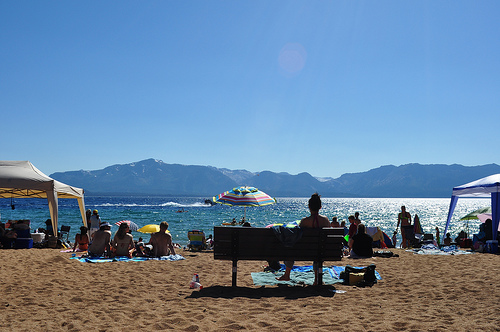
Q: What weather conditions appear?
A: It is cloudless.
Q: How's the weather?
A: It is cloudless.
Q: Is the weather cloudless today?
A: Yes, it is cloudless.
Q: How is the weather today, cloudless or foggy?
A: It is cloudless.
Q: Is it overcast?
A: No, it is cloudless.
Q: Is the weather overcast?
A: No, it is cloudless.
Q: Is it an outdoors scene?
A: Yes, it is outdoors.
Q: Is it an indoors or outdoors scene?
A: It is outdoors.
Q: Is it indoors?
A: No, it is outdoors.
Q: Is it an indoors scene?
A: No, it is outdoors.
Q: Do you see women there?
A: Yes, there is a woman.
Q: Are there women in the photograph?
A: Yes, there is a woman.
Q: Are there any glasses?
A: No, there are no glasses.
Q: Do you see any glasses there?
A: No, there are no glasses.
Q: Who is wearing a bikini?
A: The woman is wearing a bikini.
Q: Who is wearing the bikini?
A: The woman is wearing a bikini.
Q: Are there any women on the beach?
A: Yes, there is a woman on the beach.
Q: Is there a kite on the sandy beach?
A: No, there is a woman on the beach.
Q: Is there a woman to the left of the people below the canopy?
A: Yes, there is a woman to the left of the people.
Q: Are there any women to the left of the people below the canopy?
A: Yes, there is a woman to the left of the people.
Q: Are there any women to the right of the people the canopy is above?
A: No, the woman is to the left of the people.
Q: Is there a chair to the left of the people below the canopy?
A: No, there is a woman to the left of the people.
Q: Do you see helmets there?
A: No, there are no helmets.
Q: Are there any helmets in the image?
A: No, there are no helmets.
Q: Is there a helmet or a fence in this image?
A: No, there are no helmets or fences.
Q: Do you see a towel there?
A: Yes, there is a towel.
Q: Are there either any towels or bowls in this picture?
A: Yes, there is a towel.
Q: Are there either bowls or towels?
A: Yes, there is a towel.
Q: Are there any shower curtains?
A: No, there are no shower curtains.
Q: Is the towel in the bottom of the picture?
A: Yes, the towel is in the bottom of the image.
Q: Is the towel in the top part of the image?
A: No, the towel is in the bottom of the image.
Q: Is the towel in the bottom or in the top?
A: The towel is in the bottom of the image.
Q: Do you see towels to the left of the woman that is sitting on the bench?
A: Yes, there is a towel to the left of the woman.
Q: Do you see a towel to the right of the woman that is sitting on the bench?
A: No, the towel is to the left of the woman.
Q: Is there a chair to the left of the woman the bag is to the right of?
A: No, there is a towel to the left of the woman.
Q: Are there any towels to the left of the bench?
A: Yes, there is a towel to the left of the bench.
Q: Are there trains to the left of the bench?
A: No, there is a towel to the left of the bench.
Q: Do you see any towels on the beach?
A: Yes, there is a towel on the beach.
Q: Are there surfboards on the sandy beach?
A: No, there is a towel on the beach.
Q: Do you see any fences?
A: No, there are no fences.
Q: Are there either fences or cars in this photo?
A: No, there are no fences or cars.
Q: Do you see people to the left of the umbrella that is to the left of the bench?
A: Yes, there are people to the left of the umbrella.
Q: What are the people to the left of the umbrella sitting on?
A: The people are sitting on the towel.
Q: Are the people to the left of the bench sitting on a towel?
A: Yes, the people are sitting on a towel.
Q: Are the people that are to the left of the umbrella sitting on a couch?
A: No, the people are sitting on a towel.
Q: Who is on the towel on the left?
A: The people are on the towel.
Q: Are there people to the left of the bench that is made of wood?
A: Yes, there are people to the left of the bench.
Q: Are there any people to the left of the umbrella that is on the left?
A: Yes, there are people to the left of the umbrella.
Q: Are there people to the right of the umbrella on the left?
A: No, the people are to the left of the umbrella.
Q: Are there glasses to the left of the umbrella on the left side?
A: No, there are people to the left of the umbrella.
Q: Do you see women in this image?
A: Yes, there is a woman.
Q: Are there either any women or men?
A: Yes, there is a woman.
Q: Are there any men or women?
A: Yes, there is a woman.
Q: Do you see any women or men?
A: Yes, there is a woman.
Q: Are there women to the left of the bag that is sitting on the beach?
A: Yes, there is a woman to the left of the bag.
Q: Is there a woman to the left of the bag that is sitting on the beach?
A: Yes, there is a woman to the left of the bag.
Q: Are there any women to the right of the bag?
A: No, the woman is to the left of the bag.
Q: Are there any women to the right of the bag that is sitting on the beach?
A: No, the woman is to the left of the bag.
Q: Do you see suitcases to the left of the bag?
A: No, there is a woman to the left of the bag.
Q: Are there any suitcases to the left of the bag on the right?
A: No, there is a woman to the left of the bag.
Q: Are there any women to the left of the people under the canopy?
A: Yes, there is a woman to the left of the people.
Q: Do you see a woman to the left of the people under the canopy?
A: Yes, there is a woman to the left of the people.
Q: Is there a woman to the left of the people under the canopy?
A: Yes, there is a woman to the left of the people.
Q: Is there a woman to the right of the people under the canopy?
A: No, the woman is to the left of the people.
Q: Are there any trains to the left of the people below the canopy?
A: No, there is a woman to the left of the people.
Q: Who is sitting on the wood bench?
A: The woman is sitting on the bench.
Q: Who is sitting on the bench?
A: The woman is sitting on the bench.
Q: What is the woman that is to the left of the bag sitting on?
A: The woman is sitting on the bench.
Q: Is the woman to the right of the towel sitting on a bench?
A: Yes, the woman is sitting on a bench.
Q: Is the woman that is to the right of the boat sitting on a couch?
A: No, the woman is sitting on a bench.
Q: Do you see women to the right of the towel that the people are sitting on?
A: Yes, there is a woman to the right of the towel.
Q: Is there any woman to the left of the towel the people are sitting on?
A: No, the woman is to the right of the towel.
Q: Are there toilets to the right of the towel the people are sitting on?
A: No, there is a woman to the right of the towel.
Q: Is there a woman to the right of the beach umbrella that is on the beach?
A: Yes, there is a woman to the right of the beach umbrella.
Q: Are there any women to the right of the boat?
A: Yes, there is a woman to the right of the boat.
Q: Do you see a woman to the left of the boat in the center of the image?
A: No, the woman is to the right of the boat.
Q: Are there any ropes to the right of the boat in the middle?
A: No, there is a woman to the right of the boat.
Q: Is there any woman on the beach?
A: Yes, there is a woman on the beach.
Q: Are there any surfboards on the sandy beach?
A: No, there is a woman on the beach.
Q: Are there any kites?
A: No, there are no kites.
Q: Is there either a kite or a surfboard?
A: No, there are no kites or surfboards.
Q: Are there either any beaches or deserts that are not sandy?
A: No, there is a beach but it is sandy.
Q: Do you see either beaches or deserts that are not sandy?
A: No, there is a beach but it is sandy.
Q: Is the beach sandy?
A: Yes, the beach is sandy.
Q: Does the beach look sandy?
A: Yes, the beach is sandy.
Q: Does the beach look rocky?
A: No, the beach is sandy.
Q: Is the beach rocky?
A: No, the beach is sandy.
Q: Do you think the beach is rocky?
A: No, the beach is sandy.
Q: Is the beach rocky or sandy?
A: The beach is sandy.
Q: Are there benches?
A: Yes, there is a bench.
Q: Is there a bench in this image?
A: Yes, there is a bench.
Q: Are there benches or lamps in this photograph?
A: Yes, there is a bench.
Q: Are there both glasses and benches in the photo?
A: No, there is a bench but no glasses.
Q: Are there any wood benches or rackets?
A: Yes, there is a wood bench.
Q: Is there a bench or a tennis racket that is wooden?
A: Yes, the bench is wooden.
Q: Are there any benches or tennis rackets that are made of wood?
A: Yes, the bench is made of wood.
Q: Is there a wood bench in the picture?
A: Yes, there is a wood bench.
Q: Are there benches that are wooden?
A: Yes, there is a bench that is wooden.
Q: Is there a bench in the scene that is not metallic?
A: Yes, there is a wooden bench.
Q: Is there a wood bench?
A: Yes, there is a bench that is made of wood.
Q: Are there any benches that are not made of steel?
A: Yes, there is a bench that is made of wood.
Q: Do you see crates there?
A: No, there are no crates.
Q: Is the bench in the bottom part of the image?
A: Yes, the bench is in the bottom of the image.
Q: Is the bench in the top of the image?
A: No, the bench is in the bottom of the image.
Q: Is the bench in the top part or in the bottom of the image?
A: The bench is in the bottom of the image.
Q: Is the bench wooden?
A: Yes, the bench is wooden.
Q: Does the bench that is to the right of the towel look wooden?
A: Yes, the bench is wooden.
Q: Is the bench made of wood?
A: Yes, the bench is made of wood.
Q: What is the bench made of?
A: The bench is made of wood.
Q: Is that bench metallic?
A: No, the bench is wooden.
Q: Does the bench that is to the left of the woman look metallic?
A: No, the bench is wooden.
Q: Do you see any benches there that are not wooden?
A: No, there is a bench but it is wooden.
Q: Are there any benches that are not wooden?
A: No, there is a bench but it is wooden.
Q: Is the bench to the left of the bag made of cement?
A: No, the bench is made of wood.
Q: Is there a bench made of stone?
A: No, there is a bench but it is made of wood.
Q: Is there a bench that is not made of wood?
A: No, there is a bench but it is made of wood.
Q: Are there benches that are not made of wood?
A: No, there is a bench but it is made of wood.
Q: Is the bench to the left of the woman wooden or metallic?
A: The bench is wooden.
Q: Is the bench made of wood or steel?
A: The bench is made of wood.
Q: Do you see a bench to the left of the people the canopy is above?
A: Yes, there is a bench to the left of the people.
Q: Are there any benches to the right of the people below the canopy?
A: No, the bench is to the left of the people.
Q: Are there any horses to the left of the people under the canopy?
A: No, there is a bench to the left of the people.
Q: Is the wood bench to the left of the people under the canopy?
A: Yes, the bench is to the left of the people.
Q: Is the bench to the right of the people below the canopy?
A: No, the bench is to the left of the people.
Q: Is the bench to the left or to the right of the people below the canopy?
A: The bench is to the left of the people.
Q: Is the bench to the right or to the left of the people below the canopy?
A: The bench is to the left of the people.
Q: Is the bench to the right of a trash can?
A: No, the bench is to the right of the umbrella.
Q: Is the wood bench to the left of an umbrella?
A: No, the bench is to the right of an umbrella.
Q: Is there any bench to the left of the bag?
A: Yes, there is a bench to the left of the bag.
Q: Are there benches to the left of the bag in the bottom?
A: Yes, there is a bench to the left of the bag.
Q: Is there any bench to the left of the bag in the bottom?
A: Yes, there is a bench to the left of the bag.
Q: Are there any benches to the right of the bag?
A: No, the bench is to the left of the bag.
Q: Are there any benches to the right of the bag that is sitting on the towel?
A: No, the bench is to the left of the bag.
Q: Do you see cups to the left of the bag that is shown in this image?
A: No, there is a bench to the left of the bag.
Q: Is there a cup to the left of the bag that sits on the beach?
A: No, there is a bench to the left of the bag.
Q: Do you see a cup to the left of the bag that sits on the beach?
A: No, there is a bench to the left of the bag.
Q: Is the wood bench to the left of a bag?
A: Yes, the bench is to the left of a bag.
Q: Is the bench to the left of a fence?
A: No, the bench is to the left of a bag.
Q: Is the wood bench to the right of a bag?
A: No, the bench is to the left of a bag.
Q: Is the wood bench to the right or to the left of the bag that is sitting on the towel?
A: The bench is to the left of the bag.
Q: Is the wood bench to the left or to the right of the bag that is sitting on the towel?
A: The bench is to the left of the bag.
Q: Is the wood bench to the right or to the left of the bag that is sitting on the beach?
A: The bench is to the left of the bag.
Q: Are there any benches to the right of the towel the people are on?
A: Yes, there is a bench to the right of the towel.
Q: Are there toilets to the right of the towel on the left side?
A: No, there is a bench to the right of the towel.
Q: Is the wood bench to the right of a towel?
A: Yes, the bench is to the right of a towel.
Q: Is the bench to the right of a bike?
A: No, the bench is to the right of a towel.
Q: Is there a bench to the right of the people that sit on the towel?
A: Yes, there is a bench to the right of the people.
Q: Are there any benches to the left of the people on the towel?
A: No, the bench is to the right of the people.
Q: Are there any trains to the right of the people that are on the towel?
A: No, there is a bench to the right of the people.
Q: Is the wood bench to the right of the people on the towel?
A: Yes, the bench is to the right of the people.